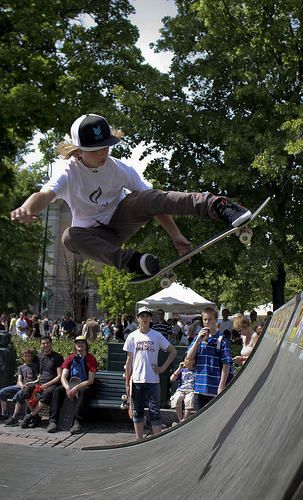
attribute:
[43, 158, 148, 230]
shirt — white, red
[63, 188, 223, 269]
pants — brown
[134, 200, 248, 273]
shoes — black, white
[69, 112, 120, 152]
hat — black, white, blue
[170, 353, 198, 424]
man — sitting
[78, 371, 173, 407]
bench' — green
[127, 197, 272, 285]
skateboard — black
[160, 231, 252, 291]
wheels — white, round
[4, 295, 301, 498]
ramp — black, gray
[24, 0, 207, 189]
sky — blue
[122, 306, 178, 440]
person — drinking, standing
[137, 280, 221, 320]
tent — white